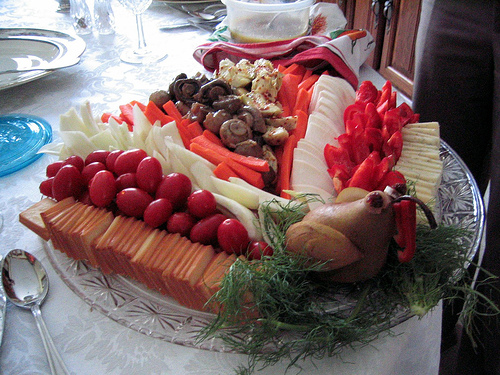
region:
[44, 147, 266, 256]
a pile of red grape tomatoes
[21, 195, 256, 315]
some sliced smoked cheese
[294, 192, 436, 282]
a big yellow pear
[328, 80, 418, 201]
some sliced red peppers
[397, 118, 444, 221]
a stack of sliced cheese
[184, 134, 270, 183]
some sliced orange carrots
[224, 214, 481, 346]
a pile of fresh dill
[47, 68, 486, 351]
a large glass platter with food on it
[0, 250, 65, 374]
a silver table spoon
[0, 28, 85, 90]
a large plate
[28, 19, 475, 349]
platter of food shaped like a chicken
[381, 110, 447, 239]
row of crackers on platter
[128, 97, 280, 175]
raw cut carrots on platter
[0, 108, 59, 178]
blue plastic container lid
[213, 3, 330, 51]
clear plastic container on table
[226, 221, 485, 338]
dill herb on platter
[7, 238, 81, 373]
silver spoon on table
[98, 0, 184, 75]
stemmed wine glass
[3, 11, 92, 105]
round dinner plate and utensil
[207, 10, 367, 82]
dish cloth under bowl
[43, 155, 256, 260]
a group of tiny grape tomatoes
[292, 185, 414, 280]
a pear made to look like a bird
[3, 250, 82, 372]
the spoon sitting on the table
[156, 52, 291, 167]
assorted pieces of food on the plate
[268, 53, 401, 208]
sliced up veggies on the plate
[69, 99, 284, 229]
more sliced veggies on the plate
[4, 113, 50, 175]
a lid for a tupperware container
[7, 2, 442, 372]
a table filled with food and plates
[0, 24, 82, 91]
a plate sitting on the table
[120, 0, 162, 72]
the bottom half of a wine glass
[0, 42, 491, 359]
The plate holds a lot of food.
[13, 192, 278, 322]
Cheese is on the plate.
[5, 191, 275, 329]
The cheese is sliced.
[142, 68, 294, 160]
Mushrooms are on the plate.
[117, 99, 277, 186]
Red peppers are on the plate.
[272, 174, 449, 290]
A pear is on the plate.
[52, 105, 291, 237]
Sliced vegetables are on the plate.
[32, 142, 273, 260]
A pink food is on the plate.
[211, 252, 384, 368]
Garnish is on the plate.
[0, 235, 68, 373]
A spoon is next to the plate.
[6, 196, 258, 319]
sliced cheese on clear serving platter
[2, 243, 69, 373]
silver spoon on white table cloth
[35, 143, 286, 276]
red olives on serving plate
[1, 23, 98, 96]
white plate on table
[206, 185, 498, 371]
green garnish on cheese platter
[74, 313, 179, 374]
white patterned table cloth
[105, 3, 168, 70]
bottom part of glass on table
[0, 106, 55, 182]
round blue plastic container lid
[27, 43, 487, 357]
serving platter with several types of cheese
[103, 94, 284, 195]
sliced carrots on snack tray